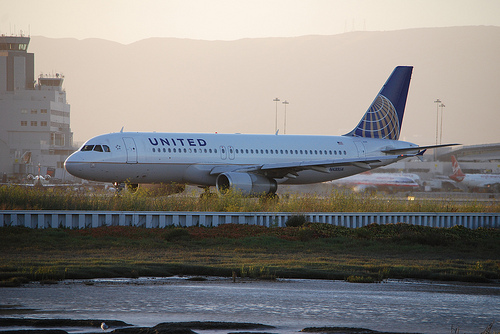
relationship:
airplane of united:
[83, 125, 408, 187] [150, 135, 212, 145]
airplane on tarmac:
[83, 125, 408, 187] [80, 194, 119, 201]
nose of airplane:
[58, 158, 82, 170] [83, 125, 408, 187]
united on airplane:
[150, 135, 212, 145] [83, 125, 408, 187]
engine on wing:
[211, 174, 264, 197] [247, 157, 400, 181]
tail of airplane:
[359, 59, 414, 152] [83, 125, 408, 187]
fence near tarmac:
[99, 206, 157, 234] [80, 194, 119, 201]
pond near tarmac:
[126, 293, 166, 313] [80, 194, 119, 201]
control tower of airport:
[13, 83, 53, 145] [458, 142, 487, 167]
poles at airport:
[263, 106, 290, 132] [458, 142, 487, 167]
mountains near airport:
[165, 52, 274, 83] [458, 142, 487, 167]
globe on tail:
[357, 98, 397, 136] [359, 59, 414, 152]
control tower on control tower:
[13, 83, 53, 145] [0, 24, 82, 183]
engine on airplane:
[211, 174, 264, 197] [83, 125, 408, 187]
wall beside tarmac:
[333, 209, 392, 233] [80, 194, 119, 201]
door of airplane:
[120, 131, 137, 168] [83, 125, 408, 187]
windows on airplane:
[76, 141, 109, 154] [83, 125, 408, 187]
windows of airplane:
[76, 141, 109, 154] [83, 125, 408, 187]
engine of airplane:
[211, 174, 264, 197] [83, 125, 408, 187]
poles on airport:
[263, 106, 290, 132] [458, 142, 487, 167]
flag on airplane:
[397, 175, 412, 182] [83, 125, 408, 187]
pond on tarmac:
[126, 293, 166, 313] [80, 194, 119, 201]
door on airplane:
[120, 131, 137, 168] [83, 125, 408, 187]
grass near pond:
[114, 196, 155, 211] [126, 293, 166, 313]